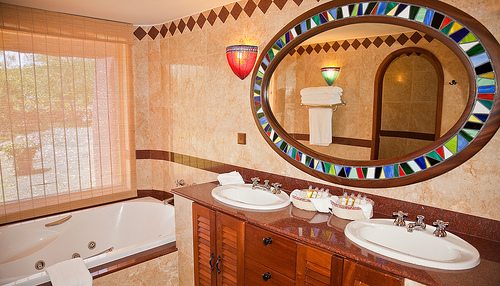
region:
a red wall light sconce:
[222, 40, 258, 82]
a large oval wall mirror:
[247, 1, 497, 185]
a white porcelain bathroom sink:
[211, 169, 291, 219]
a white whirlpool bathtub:
[1, 193, 173, 282]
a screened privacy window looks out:
[3, 8, 137, 213]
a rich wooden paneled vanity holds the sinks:
[171, 172, 496, 284]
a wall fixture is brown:
[232, 128, 251, 148]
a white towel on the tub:
[36, 245, 99, 283]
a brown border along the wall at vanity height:
[136, 148, 499, 241]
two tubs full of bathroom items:
[288, 180, 374, 220]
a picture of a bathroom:
[19, 19, 461, 269]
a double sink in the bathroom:
[217, 154, 478, 271]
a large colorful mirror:
[240, 12, 487, 197]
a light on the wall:
[213, 34, 278, 106]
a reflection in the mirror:
[293, 50, 453, 153]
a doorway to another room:
[364, 37, 450, 145]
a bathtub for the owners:
[1, 189, 187, 282]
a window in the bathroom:
[13, 39, 150, 218]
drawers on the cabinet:
[179, 208, 369, 282]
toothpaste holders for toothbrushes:
[299, 182, 374, 220]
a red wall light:
[221, 38, 263, 81]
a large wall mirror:
[246, 1, 498, 189]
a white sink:
[346, 211, 481, 274]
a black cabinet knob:
[258, 235, 271, 246]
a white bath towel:
[305, 105, 332, 144]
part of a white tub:
[2, 194, 178, 284]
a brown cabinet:
[189, 205, 243, 285]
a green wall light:
[321, 61, 341, 85]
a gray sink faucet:
[390, 205, 450, 238]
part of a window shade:
[0, 3, 142, 223]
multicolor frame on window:
[240, 8, 492, 194]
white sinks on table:
[212, 167, 462, 282]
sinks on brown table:
[203, 152, 449, 284]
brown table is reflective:
[272, 206, 355, 280]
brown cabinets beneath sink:
[191, 218, 328, 285]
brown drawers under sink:
[252, 223, 312, 285]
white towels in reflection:
[291, 76, 340, 131]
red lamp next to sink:
[216, 21, 258, 83]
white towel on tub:
[29, 238, 131, 285]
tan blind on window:
[0, 21, 152, 196]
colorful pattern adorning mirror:
[253, 4, 498, 207]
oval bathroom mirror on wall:
[233, 0, 495, 192]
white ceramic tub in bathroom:
[0, 183, 227, 284]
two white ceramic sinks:
[201, 158, 484, 283]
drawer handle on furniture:
[254, 271, 278, 281]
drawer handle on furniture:
[258, 230, 274, 245]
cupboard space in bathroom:
[178, 200, 245, 282]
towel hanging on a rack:
[299, 101, 351, 152]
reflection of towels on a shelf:
[294, 85, 354, 110]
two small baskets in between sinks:
[287, 178, 384, 223]